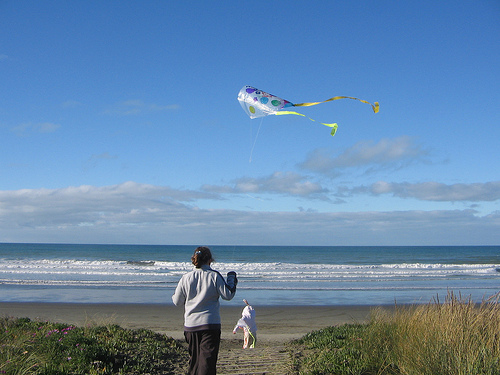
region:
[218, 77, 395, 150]
kites in the sky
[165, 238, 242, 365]
woman flying a kite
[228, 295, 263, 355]
man with a kite on beach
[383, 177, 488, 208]
cloud in the sky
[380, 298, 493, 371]
tall grasses on a beach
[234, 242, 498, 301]
ocean water in the distance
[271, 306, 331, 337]
sand on a beach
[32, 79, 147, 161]
blue sky in the background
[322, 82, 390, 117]
tail of a kite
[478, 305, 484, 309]
part of a grass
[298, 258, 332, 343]
part of the ocean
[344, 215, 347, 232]
part of a cloud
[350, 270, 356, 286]
part of the sea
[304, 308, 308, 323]
edge of a sea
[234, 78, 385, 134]
kite in the air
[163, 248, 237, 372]
woman is flying a kite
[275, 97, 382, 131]
two yellow tails flying horizontally from the kite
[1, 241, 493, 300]
large span of ocean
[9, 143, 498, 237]
stratus clouds on the horizon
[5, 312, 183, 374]
shrubs on the beach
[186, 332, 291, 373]
pathway area in the sand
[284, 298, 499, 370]
shrubs on the left of the pathway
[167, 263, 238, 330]
the woman is wearing a gray long sleeved shirt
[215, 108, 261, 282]
string of the kite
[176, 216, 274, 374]
two peopl at the beach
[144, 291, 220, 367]
pants are black in color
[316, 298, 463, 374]
grases are beside th ocean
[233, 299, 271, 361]
a person is flying the kite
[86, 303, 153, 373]
the plants ate green in color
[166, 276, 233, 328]
the sweater is gray in color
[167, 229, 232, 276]
the hair is pon tailed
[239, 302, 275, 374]
a person is dresseed in white cloths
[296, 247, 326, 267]
water is blue in color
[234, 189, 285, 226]
sky i scoverd of clouds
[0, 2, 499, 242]
blue of daytime sky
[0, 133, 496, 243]
clouds low in sky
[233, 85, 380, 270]
flying kite on string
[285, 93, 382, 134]
two tails on kite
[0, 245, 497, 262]
surface of blue water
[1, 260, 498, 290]
white caps of crashing waves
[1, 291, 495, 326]
wet sand on shore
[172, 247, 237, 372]
back of woman in jacket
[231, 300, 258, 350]
white dog on sand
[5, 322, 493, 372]
grass on sand dunes